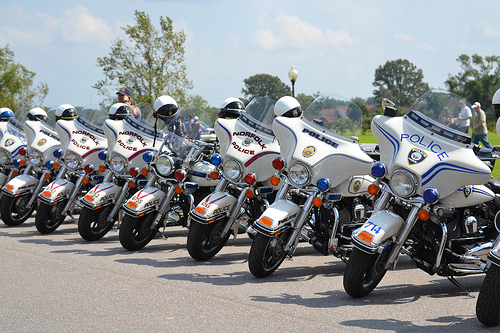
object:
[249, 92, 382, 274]
motorcycle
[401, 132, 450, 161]
writing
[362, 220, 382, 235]
number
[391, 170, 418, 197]
headlight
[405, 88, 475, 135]
shield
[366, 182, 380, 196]
light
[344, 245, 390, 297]
tire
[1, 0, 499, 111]
sky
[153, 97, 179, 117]
helmet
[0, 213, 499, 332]
road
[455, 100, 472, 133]
man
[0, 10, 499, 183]
park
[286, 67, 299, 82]
light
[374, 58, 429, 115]
tree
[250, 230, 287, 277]
front wheel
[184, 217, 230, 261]
wheel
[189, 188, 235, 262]
front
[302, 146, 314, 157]
symbol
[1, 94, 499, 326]
row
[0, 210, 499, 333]
ground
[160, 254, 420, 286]
shadow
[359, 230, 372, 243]
reflector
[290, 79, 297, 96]
post